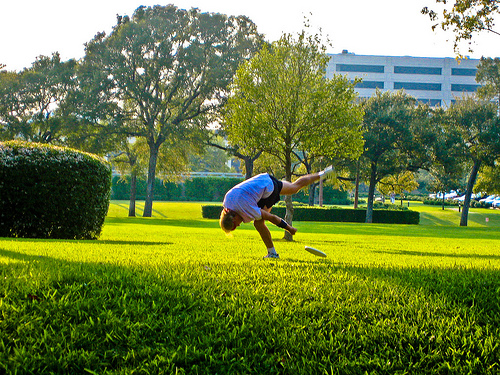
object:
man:
[218, 161, 339, 261]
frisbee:
[304, 243, 329, 262]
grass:
[0, 199, 499, 272]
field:
[0, 202, 498, 374]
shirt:
[221, 173, 275, 223]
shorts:
[259, 166, 284, 210]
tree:
[223, 12, 367, 241]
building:
[318, 49, 499, 189]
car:
[476, 192, 499, 207]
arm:
[244, 202, 298, 238]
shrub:
[1, 137, 115, 248]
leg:
[272, 160, 337, 197]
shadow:
[93, 234, 178, 254]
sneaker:
[324, 161, 340, 183]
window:
[333, 63, 387, 75]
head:
[216, 207, 244, 236]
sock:
[316, 169, 328, 185]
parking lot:
[428, 184, 500, 210]